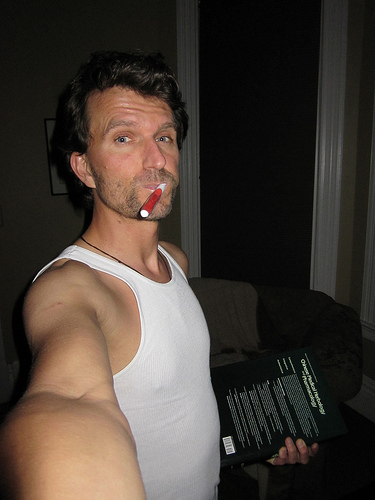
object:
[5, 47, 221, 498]
man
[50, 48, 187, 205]
hair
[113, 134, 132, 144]
eye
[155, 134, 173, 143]
eye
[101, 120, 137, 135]
eyebrow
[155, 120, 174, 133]
eyebrow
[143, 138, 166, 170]
nose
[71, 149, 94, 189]
ear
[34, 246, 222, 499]
shirt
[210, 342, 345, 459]
book